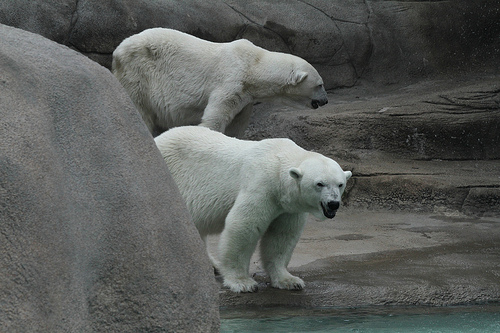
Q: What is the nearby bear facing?
A: A camera.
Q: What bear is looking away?
A: The top one.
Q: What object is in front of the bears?
A: A large boulder.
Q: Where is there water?
A: In front.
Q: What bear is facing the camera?
A: The front one.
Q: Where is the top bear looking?
A: At the steps.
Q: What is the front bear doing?
A: Making a face.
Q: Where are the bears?
A: In an enclosure.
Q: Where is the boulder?
A: To the left.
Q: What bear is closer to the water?
A: The bottom.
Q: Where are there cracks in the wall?
A: In the back.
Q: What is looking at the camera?
A: Polar bear.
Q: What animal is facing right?
A: Polar bear.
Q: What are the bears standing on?
A: Rocks.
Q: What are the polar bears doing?
A: Standing.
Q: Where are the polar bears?
A: Near water.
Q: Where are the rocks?
A: Under the polar bears.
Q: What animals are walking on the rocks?
A: Polar bears.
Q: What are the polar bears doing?
A: Standing.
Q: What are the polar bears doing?
A: Standing up.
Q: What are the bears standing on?
A: Rocks.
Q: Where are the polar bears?
A: In a rocky enclosure.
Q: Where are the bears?
A: In an enclosed area.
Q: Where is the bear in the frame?
A: Near the water.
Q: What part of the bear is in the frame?
A: His front part.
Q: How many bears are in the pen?
A: Two.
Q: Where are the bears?
A: Near the water.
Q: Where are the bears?
A: On the rocks.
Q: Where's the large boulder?
A: In front of the bear.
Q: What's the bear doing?
A: Standing near the boulder.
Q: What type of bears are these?
A: Polar bears.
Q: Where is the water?
A: In front of the bears.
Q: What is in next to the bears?
A: A big solid rock.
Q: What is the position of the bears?
A: Different.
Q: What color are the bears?
A: White.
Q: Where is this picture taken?
A: A zoo.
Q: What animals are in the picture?
A: Polar bears.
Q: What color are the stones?
A: Grey.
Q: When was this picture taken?
A: Daytime.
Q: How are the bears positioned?
A: Standing.